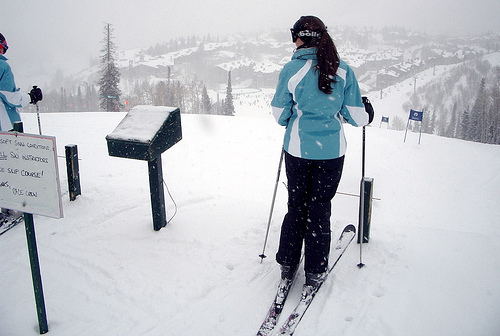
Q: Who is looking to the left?
A: Woman skier.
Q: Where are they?
A: On top mountain.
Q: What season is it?
A: Winter.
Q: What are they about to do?
A: Race.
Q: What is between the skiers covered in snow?
A: Podium.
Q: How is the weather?
A: Cold and snowing.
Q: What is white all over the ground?
A: Snow.